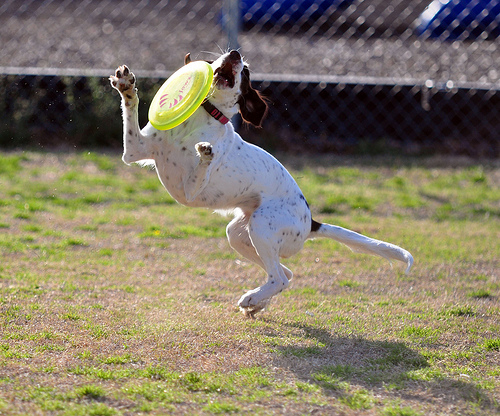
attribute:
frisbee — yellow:
[141, 48, 219, 142]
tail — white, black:
[308, 210, 424, 282]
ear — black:
[237, 74, 271, 135]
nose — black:
[222, 43, 243, 72]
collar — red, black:
[199, 103, 233, 128]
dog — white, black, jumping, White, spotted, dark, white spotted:
[101, 35, 421, 325]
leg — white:
[237, 208, 297, 324]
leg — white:
[184, 130, 220, 200]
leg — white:
[99, 57, 155, 171]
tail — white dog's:
[303, 206, 424, 275]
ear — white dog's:
[243, 70, 267, 125]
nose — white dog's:
[215, 44, 253, 72]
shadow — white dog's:
[267, 310, 471, 413]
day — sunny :
[42, 20, 464, 400]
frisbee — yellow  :
[142, 53, 223, 135]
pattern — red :
[154, 80, 188, 107]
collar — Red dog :
[204, 94, 226, 122]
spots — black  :
[264, 190, 314, 215]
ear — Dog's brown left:
[238, 72, 268, 129]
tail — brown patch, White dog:
[311, 213, 419, 283]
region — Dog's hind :
[296, 201, 312, 258]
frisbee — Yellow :
[150, 60, 215, 123]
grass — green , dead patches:
[31, 300, 309, 399]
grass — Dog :
[138, 365, 218, 395]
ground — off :
[220, 327, 289, 357]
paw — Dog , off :
[231, 292, 258, 322]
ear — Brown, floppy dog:
[238, 75, 270, 128]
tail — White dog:
[305, 211, 427, 271]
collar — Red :
[201, 100, 232, 128]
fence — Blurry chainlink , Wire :
[4, 1, 484, 164]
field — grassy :
[466, 398, 468, 399]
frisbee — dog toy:
[143, 53, 216, 134]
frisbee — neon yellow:
[148, 56, 216, 116]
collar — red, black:
[198, 94, 233, 132]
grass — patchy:
[2, 149, 492, 413]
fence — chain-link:
[4, 1, 497, 181]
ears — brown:
[228, 62, 270, 132]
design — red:
[152, 78, 192, 111]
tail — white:
[305, 214, 416, 271]